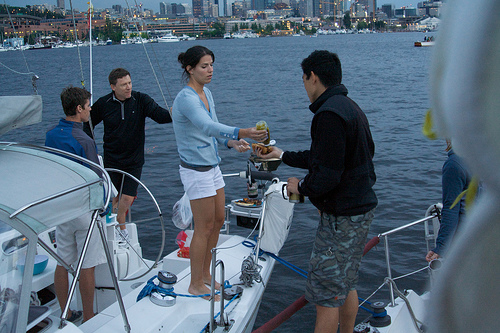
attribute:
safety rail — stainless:
[253, 200, 453, 330]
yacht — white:
[154, 29, 184, 44]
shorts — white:
[175, 159, 227, 205]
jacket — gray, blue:
[40, 116, 108, 218]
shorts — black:
[100, 152, 150, 196]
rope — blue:
[231, 241, 392, 331]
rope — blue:
[123, 269, 243, 302]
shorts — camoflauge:
[302, 207, 376, 308]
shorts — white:
[171, 159, 224, 209]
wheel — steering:
[83, 159, 186, 303]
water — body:
[21, 45, 481, 236]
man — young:
[35, 88, 129, 328]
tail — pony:
[169, 47, 189, 70]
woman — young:
[160, 30, 275, 300]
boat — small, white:
[5, 59, 311, 331]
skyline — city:
[6, 2, 481, 52]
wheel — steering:
[77, 155, 197, 300]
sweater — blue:
[168, 87, 238, 165]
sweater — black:
[283, 84, 381, 213]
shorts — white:
[53, 211, 105, 267]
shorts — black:
[84, 67, 173, 225]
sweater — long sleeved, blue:
[172, 82, 239, 169]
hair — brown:
[175, 45, 213, 75]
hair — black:
[301, 47, 342, 88]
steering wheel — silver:
[99, 167, 168, 288]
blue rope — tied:
[266, 253, 356, 295]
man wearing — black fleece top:
[272, 47, 389, 212]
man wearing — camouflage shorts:
[284, 39, 392, 318]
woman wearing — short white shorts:
[157, 40, 232, 304]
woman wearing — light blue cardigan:
[172, 48, 240, 314]